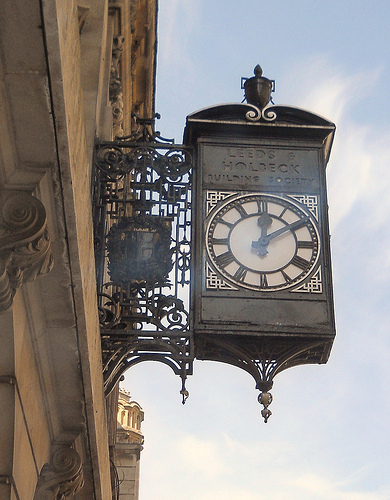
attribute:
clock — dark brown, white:
[182, 58, 340, 365]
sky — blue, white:
[158, 3, 381, 68]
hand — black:
[262, 212, 315, 244]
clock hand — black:
[258, 211, 311, 245]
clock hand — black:
[254, 207, 270, 254]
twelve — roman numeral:
[256, 197, 267, 212]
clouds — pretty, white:
[302, 65, 353, 106]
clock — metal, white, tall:
[204, 189, 323, 294]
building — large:
[18, 0, 101, 452]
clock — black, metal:
[179, 164, 343, 303]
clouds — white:
[288, 10, 386, 129]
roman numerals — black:
[277, 204, 288, 217]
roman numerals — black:
[291, 218, 307, 229]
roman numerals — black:
[294, 239, 315, 250]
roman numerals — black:
[290, 253, 310, 270]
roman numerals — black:
[280, 268, 292, 282]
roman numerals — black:
[257, 271, 270, 288]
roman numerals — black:
[230, 263, 247, 283]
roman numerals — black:
[215, 249, 233, 269]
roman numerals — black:
[210, 236, 229, 246]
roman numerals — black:
[216, 217, 233, 229]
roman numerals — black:
[234, 203, 247, 218]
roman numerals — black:
[255, 198, 268, 213]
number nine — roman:
[209, 236, 229, 247]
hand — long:
[262, 215, 308, 242]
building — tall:
[2, 2, 174, 365]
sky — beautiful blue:
[121, 0, 388, 499]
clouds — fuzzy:
[111, 7, 388, 489]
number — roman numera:
[253, 197, 270, 215]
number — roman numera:
[276, 202, 292, 221]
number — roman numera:
[290, 215, 308, 233]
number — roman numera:
[291, 234, 316, 251]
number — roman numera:
[289, 256, 312, 273]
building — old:
[7, 18, 162, 360]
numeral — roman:
[277, 268, 293, 289]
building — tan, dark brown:
[2, 1, 163, 498]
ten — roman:
[213, 211, 235, 228]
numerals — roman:
[224, 258, 334, 299]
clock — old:
[96, 50, 358, 424]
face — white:
[212, 194, 319, 291]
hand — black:
[254, 193, 271, 258]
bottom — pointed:
[192, 329, 336, 431]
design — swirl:
[242, 96, 278, 124]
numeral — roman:
[288, 252, 312, 276]